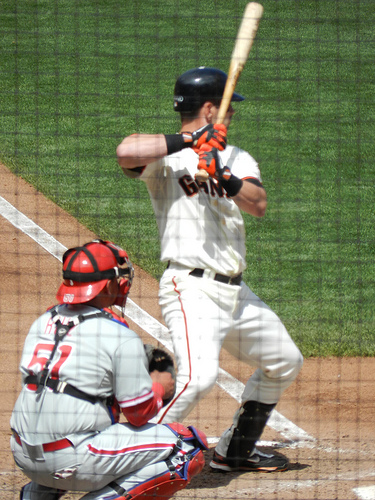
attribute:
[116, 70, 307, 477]
batter — waiting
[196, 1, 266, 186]
bat — wooden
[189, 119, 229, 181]
gloves — orange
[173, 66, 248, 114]
helmet — hard, black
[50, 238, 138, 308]
cap — red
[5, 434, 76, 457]
belt — red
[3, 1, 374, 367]
grass — green, infield, gree, maicured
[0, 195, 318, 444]
line — chalk, section, white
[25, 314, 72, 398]
letters — red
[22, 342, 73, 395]
number — 51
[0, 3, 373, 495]
field — dirt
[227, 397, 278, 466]
shin guard — black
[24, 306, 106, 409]
straps — black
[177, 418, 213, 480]
knee guard — hard, red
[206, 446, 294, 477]
cleats — black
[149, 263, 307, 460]
pants — white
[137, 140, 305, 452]
uniform — white